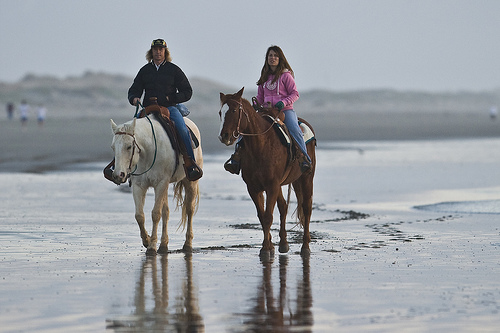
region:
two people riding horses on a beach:
[97, 36, 328, 264]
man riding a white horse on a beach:
[102, 34, 205, 256]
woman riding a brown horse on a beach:
[212, 44, 332, 252]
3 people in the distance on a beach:
[2, 95, 47, 126]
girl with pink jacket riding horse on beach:
[210, 40, 315, 260]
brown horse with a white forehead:
[210, 86, 250, 146]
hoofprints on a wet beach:
[335, 206, 461, 251]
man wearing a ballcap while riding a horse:
[100, 35, 202, 262]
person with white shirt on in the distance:
[32, 97, 47, 124]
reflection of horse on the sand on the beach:
[107, 259, 211, 331]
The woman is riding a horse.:
[214, 33, 317, 265]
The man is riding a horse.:
[102, 33, 212, 260]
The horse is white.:
[108, 110, 206, 258]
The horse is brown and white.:
[218, 88, 319, 262]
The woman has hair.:
[252, 40, 299, 116]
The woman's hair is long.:
[253, 40, 300, 113]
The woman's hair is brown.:
[256, 39, 296, 91]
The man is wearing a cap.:
[126, 35, 193, 110]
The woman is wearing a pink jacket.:
[249, 41, 301, 115]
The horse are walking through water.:
[63, 23, 393, 331]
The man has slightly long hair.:
[124, 33, 194, 115]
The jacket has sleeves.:
[248, 42, 300, 118]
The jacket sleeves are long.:
[248, 38, 299, 117]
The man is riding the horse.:
[94, 32, 210, 258]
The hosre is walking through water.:
[0, 28, 219, 331]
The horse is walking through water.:
[209, 39, 499, 331]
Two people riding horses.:
[16, 32, 476, 322]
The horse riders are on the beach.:
[82, 40, 390, 261]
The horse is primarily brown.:
[219, 86, 319, 261]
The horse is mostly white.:
[103, 118, 211, 243]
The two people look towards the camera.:
[109, 32, 350, 156]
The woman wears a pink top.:
[257, 71, 296, 117]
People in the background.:
[5, 98, 58, 128]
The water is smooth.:
[376, 153, 463, 308]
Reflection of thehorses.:
[112, 253, 336, 330]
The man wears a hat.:
[141, 37, 172, 47]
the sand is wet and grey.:
[316, 240, 458, 317]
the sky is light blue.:
[341, 34, 488, 80]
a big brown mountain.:
[12, 63, 119, 98]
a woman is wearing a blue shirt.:
[13, 96, 40, 143]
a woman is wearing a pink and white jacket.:
[252, 71, 292, 92]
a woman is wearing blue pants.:
[279, 117, 311, 146]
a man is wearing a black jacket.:
[143, 73, 173, 91]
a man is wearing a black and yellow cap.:
[145, 34, 174, 55]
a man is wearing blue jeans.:
[166, 116, 202, 145]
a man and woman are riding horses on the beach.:
[68, 0, 354, 270]